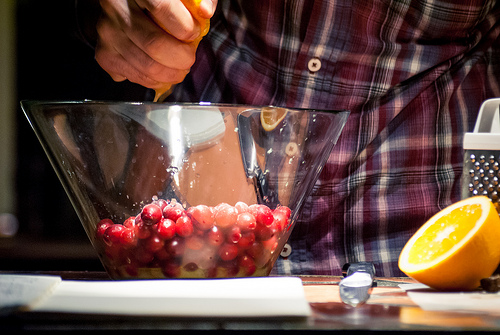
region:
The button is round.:
[309, 58, 321, 73]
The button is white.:
[304, 55, 324, 76]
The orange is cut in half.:
[396, 193, 498, 289]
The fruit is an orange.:
[386, 194, 497, 288]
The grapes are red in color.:
[91, 198, 298, 276]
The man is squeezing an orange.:
[90, 0, 215, 100]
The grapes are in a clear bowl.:
[9, 89, 354, 279]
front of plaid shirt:
[138, 2, 498, 270]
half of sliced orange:
[400, 194, 496, 286]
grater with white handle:
[460, 99, 497, 198]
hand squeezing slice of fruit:
[92, 0, 215, 87]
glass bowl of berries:
[16, 96, 346, 274]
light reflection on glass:
[20, 99, 349, 277]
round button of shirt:
[307, 58, 322, 73]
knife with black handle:
[338, 262, 376, 309]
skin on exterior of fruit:
[410, 203, 498, 289]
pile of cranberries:
[93, 198, 294, 280]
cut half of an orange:
[396, 191, 498, 289]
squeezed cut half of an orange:
[154, 0, 213, 94]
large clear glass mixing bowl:
[19, 99, 350, 279]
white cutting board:
[36, 271, 313, 328]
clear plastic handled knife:
[337, 259, 376, 310]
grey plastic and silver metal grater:
[461, 97, 498, 274]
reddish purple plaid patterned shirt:
[155, 0, 499, 273]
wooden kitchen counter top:
[0, 267, 499, 334]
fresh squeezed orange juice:
[151, 83, 170, 103]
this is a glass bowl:
[23, 56, 373, 305]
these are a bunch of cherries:
[66, 166, 325, 291]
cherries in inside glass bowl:
[28, 62, 365, 319]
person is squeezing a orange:
[85, 3, 282, 142]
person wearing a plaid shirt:
[129, 0, 474, 291]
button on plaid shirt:
[296, 38, 351, 98]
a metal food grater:
[446, 89, 497, 221]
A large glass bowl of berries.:
[19, 99, 351, 282]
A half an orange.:
[395, 195, 498, 289]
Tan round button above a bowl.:
[307, 58, 321, 73]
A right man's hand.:
[91, 1, 217, 89]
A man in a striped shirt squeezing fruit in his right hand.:
[90, 1, 499, 276]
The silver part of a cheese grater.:
[462, 149, 498, 211]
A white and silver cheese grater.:
[462, 97, 499, 213]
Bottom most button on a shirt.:
[278, 242, 292, 257]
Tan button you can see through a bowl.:
[285, 139, 297, 159]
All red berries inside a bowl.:
[90, 203, 291, 280]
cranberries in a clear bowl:
[90, 190, 291, 277]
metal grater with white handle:
[455, 91, 495, 206]